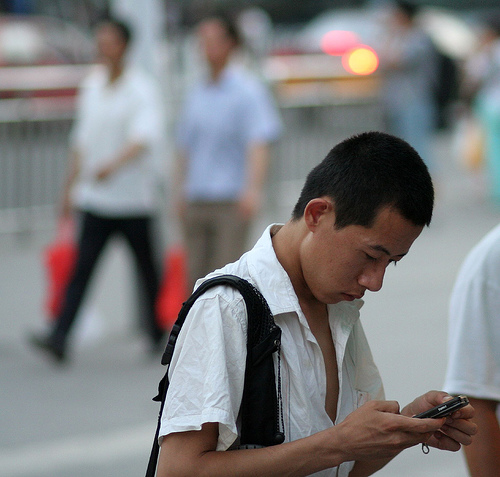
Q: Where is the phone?
A: In the man's hands.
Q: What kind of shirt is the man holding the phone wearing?
A: Button down.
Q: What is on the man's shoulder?
A: Strap.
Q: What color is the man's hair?
A: Black.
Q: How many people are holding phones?
A: 1.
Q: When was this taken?
A: Daytime.